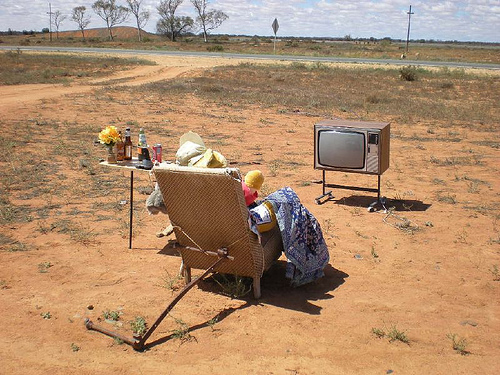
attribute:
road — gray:
[2, 40, 499, 76]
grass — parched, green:
[232, 73, 426, 104]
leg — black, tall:
[118, 170, 138, 255]